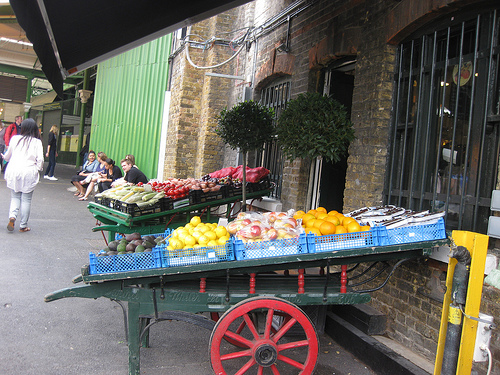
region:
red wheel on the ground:
[213, 285, 325, 370]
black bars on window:
[392, 91, 497, 181]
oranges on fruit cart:
[306, 193, 358, 246]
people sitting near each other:
[78, 124, 165, 196]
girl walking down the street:
[3, 115, 53, 241]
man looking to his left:
[116, 153, 143, 185]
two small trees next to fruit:
[218, 95, 354, 177]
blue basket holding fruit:
[83, 246, 163, 278]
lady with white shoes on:
[39, 117, 71, 206]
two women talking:
[78, 148, 103, 178]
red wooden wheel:
[209, 295, 316, 372]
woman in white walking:
[3, 118, 43, 234]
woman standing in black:
[44, 124, 59, 179]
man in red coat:
[3, 116, 23, 146]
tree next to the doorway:
[217, 99, 275, 208]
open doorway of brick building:
[319, 61, 353, 218]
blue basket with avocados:
[93, 229, 156, 272]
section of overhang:
[11, 4, 242, 95]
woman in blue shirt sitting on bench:
[71, 151, 98, 200]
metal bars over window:
[380, 10, 489, 262]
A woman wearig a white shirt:
[3, 112, 43, 239]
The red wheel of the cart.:
[202, 296, 326, 373]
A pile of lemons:
[169, 213, 228, 255]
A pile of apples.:
[228, 207, 298, 243]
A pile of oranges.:
[294, 203, 363, 237]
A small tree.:
[221, 97, 262, 211]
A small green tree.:
[287, 79, 351, 219]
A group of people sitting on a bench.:
[82, 150, 144, 207]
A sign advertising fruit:
[449, 55, 474, 91]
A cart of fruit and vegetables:
[91, 157, 278, 222]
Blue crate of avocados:
[82, 230, 168, 277]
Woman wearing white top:
[3, 117, 48, 237]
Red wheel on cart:
[183, 297, 328, 373]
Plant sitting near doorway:
[271, 91, 358, 211]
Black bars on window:
[386, 30, 498, 210]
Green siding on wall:
[105, 70, 165, 152]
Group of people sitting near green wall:
[68, 149, 148, 201]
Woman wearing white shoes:
[42, 120, 64, 185]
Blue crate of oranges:
[293, 202, 379, 252]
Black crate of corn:
[93, 182, 174, 219]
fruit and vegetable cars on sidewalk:
[32, 158, 467, 330]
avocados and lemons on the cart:
[86, 221, 273, 373]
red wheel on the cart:
[86, 226, 451, 371]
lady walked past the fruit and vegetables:
[0, 96, 184, 361]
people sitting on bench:
[70, 130, 147, 209]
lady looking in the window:
[36, 103, 76, 190]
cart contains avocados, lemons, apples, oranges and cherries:
[67, 198, 437, 365]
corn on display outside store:
[98, 166, 175, 234]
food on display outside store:
[86, 119, 452, 371]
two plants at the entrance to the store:
[204, 72, 374, 230]